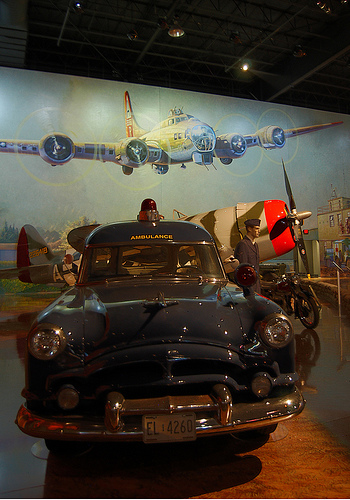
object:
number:
[187, 419, 193, 432]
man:
[234, 218, 261, 296]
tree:
[0, 224, 19, 244]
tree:
[49, 216, 96, 247]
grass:
[0, 316, 26, 340]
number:
[173, 420, 179, 433]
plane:
[0, 65, 350, 272]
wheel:
[296, 295, 319, 329]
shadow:
[296, 327, 320, 395]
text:
[131, 235, 173, 240]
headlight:
[264, 316, 292, 348]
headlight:
[29, 326, 61, 360]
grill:
[21, 333, 297, 409]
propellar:
[281, 157, 312, 281]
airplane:
[0, 156, 312, 293]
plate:
[143, 411, 196, 443]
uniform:
[234, 234, 261, 294]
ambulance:
[15, 197, 306, 453]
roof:
[86, 219, 210, 244]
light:
[138, 198, 159, 221]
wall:
[0, 66, 350, 311]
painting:
[0, 68, 350, 276]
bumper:
[14, 384, 305, 444]